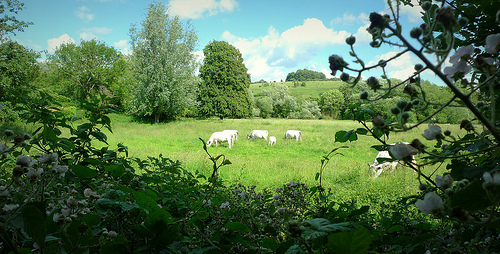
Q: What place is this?
A: It is a pasture.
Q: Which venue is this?
A: This is a pasture.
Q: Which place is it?
A: It is a pasture.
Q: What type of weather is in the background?
A: It is cloudy.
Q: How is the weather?
A: It is cloudy.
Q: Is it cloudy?
A: Yes, it is cloudy.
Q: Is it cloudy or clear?
A: It is cloudy.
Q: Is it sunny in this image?
A: No, it is cloudy.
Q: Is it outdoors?
A: Yes, it is outdoors.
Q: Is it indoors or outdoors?
A: It is outdoors.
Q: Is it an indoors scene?
A: No, it is outdoors.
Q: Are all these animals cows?
A: Yes, all the animals are cows.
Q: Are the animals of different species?
A: No, all the animals are cows.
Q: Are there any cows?
A: Yes, there is a cow.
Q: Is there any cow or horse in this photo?
A: Yes, there is a cow.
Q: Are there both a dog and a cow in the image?
A: No, there is a cow but no dogs.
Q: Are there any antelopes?
A: No, there are no antelopes.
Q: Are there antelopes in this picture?
A: No, there are no antelopes.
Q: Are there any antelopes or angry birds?
A: No, there are no antelopes or angry birds.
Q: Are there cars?
A: No, there are no cars.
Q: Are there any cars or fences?
A: No, there are no cars or fences.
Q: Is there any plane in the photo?
A: No, there are no airplanes.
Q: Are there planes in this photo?
A: No, there are no planes.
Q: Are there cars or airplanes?
A: No, there are no airplanes or cars.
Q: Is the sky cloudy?
A: Yes, the sky is cloudy.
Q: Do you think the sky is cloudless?
A: No, the sky is cloudy.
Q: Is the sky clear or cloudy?
A: The sky is cloudy.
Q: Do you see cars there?
A: No, there are no cars.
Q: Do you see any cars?
A: No, there are no cars.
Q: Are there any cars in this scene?
A: No, there are no cars.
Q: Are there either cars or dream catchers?
A: No, there are no cars or dream catchers.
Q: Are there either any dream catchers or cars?
A: No, there are no cars or dream catchers.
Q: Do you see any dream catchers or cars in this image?
A: No, there are no cars or dream catchers.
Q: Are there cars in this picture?
A: No, there are no cars.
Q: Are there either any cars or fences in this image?
A: No, there are no cars or fences.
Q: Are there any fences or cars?
A: No, there are no cars or fences.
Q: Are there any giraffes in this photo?
A: No, there are no giraffes.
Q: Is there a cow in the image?
A: Yes, there are cows.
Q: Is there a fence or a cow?
A: Yes, there are cows.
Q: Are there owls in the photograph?
A: No, there are no owls.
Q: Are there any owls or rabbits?
A: No, there are no owls or rabbits.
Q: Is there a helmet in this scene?
A: No, there are no helmets.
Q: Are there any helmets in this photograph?
A: No, there are no helmets.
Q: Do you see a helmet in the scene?
A: No, there are no helmets.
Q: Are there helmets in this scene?
A: No, there are no helmets.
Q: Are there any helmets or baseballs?
A: No, there are no helmets or baseballs.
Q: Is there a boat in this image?
A: No, there are no boats.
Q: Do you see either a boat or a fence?
A: No, there are no boats or fences.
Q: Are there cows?
A: Yes, there is a cow.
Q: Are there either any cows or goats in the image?
A: Yes, there is a cow.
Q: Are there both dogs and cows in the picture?
A: No, there is a cow but no dogs.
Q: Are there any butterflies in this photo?
A: No, there are no butterflies.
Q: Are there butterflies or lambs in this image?
A: No, there are no butterflies or lambs.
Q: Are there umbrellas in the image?
A: No, there are no umbrellas.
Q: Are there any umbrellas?
A: No, there are no umbrellas.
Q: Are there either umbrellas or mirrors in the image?
A: No, there are no umbrellas or mirrors.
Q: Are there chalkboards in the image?
A: No, there are no chalkboards.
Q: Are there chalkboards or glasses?
A: No, there are no chalkboards or glasses.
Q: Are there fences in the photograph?
A: No, there are no fences.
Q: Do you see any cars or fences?
A: No, there are no fences or cars.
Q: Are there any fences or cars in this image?
A: No, there are no fences or cars.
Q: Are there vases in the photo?
A: No, there are no vases.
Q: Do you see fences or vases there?
A: No, there are no vases or fences.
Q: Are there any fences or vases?
A: No, there are no vases or fences.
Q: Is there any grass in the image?
A: Yes, there is grass.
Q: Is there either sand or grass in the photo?
A: Yes, there is grass.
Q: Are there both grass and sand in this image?
A: No, there is grass but no sand.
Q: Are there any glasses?
A: No, there are no glasses.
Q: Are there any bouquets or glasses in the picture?
A: No, there are no glasses or bouquets.